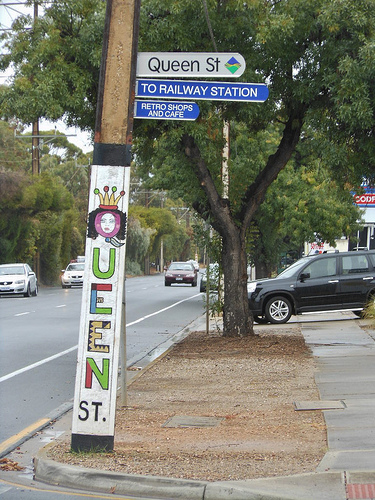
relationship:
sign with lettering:
[136, 52, 247, 77] [147, 56, 222, 73]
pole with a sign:
[69, 0, 140, 455] [136, 52, 247, 77]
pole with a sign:
[69, 0, 140, 455] [134, 77, 270, 104]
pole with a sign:
[69, 0, 140, 455] [132, 101, 201, 123]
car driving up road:
[163, 261, 199, 288] [3, 274, 200, 433]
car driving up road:
[60, 260, 83, 289] [3, 274, 200, 433]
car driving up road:
[1, 262, 40, 300] [3, 274, 200, 433]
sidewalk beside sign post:
[296, 316, 374, 499] [69, 0, 140, 455]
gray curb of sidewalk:
[32, 460, 346, 499] [296, 316, 374, 499]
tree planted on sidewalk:
[1, 2, 374, 338] [296, 316, 374, 499]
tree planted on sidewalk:
[251, 138, 366, 279] [296, 316, 374, 499]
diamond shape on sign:
[223, 56, 242, 78] [136, 52, 247, 77]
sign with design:
[136, 52, 247, 77] [223, 56, 242, 78]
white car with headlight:
[60, 260, 83, 289] [58, 272, 74, 282]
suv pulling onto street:
[248, 250, 374, 324] [3, 274, 200, 433]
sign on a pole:
[136, 52, 247, 77] [69, 0, 140, 455]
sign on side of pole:
[134, 77, 270, 104] [69, 0, 140, 455]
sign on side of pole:
[132, 101, 201, 123] [69, 0, 140, 455]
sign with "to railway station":
[134, 77, 270, 104] [140, 83, 259, 97]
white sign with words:
[70, 143, 138, 455] [75, 210, 127, 424]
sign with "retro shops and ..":
[132, 101, 201, 123] [140, 102, 193, 118]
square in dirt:
[293, 398, 346, 413] [154, 345, 308, 469]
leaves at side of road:
[1, 446, 35, 482] [0, 406, 110, 499]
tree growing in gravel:
[1, 2, 374, 338] [186, 328, 300, 366]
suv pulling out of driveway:
[248, 250, 374, 324] [203, 307, 374, 330]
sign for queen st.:
[70, 143, 138, 455] [79, 212, 121, 425]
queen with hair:
[86, 184, 128, 248] [86, 208, 128, 239]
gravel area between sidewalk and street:
[47, 330, 326, 479] [0, 273, 374, 499]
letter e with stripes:
[87, 320, 112, 352] [86, 321, 94, 355]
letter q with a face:
[94, 210, 123, 249] [99, 212, 115, 234]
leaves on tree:
[0, 2, 372, 192] [1, 2, 374, 338]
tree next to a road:
[1, 2, 374, 338] [3, 274, 200, 433]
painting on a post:
[70, 143, 138, 455] [69, 0, 140, 455]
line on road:
[1, 293, 202, 392] [3, 274, 200, 433]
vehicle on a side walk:
[248, 250, 374, 324] [296, 316, 374, 499]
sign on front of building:
[349, 184, 374, 212] [304, 177, 373, 250]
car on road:
[60, 260, 83, 289] [3, 274, 200, 433]